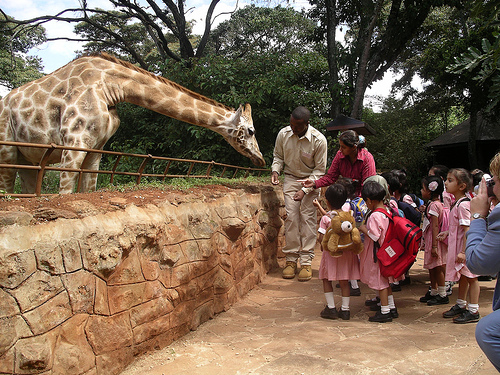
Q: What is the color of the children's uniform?
A: Pink.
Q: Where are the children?
A: At the zoo.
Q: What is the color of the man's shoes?
A: Beige.